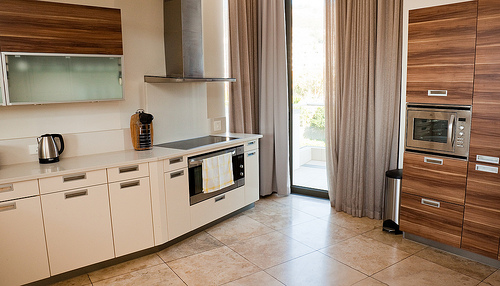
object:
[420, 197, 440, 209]
handle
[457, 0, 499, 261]
cabinet door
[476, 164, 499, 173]
handle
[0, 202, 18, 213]
handle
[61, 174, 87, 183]
handle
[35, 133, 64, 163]
kettle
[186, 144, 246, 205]
oven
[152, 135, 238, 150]
stove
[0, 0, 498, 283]
kitchen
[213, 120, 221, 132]
electrical outlet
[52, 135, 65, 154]
handle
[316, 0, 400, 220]
draperies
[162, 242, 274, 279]
tiles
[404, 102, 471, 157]
microwave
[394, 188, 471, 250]
drawers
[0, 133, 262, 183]
counter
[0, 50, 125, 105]
cabinets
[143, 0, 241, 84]
pipe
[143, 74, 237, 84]
panel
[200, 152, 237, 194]
towel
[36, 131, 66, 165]
appliances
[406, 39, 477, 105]
drawer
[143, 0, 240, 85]
duct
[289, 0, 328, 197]
door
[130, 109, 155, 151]
rack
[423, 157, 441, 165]
cabinet handle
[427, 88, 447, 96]
cabinet handle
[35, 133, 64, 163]
pot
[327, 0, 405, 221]
curtain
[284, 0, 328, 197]
window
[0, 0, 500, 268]
wall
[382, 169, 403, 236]
can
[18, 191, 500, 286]
floor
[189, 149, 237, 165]
handlebar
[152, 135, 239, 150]
top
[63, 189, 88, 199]
handle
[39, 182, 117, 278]
cabinet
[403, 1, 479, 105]
door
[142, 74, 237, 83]
shelf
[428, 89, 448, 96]
handle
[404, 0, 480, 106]
cabinet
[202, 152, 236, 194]
cloth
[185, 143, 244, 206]
door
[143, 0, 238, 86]
exhaust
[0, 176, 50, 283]
cabinets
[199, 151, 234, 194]
hand towel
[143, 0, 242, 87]
vent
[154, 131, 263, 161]
cooktop